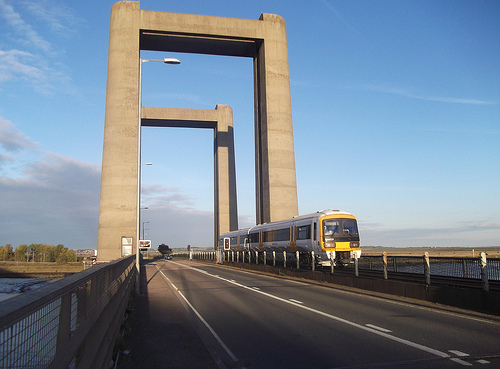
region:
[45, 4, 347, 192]
the arch is stone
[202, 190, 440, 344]
this is a train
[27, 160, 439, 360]
this is a bridge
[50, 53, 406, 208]
the sky is mostly clear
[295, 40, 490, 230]
the sky is light blue and white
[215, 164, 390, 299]
the train is yellow and white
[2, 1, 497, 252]
clouds in blue sky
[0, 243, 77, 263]
green trees on horizon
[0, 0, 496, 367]
top of paved bridge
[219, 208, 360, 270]
white and yellow commuter train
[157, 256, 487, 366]
white lines on paved road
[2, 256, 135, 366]
railing along side of bridge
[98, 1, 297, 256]
two cement structures on bridge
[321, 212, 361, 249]
windshield on front of train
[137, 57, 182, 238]
light on top of pole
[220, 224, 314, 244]
windows on side of train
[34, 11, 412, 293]
this is a highway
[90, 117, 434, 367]
this is a railroad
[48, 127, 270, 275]
this is a bridge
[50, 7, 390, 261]
the bridge has an arch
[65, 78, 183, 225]
the arch is stone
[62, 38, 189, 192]
the arch is gray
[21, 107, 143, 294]
the sky is cloudy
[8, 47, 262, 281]
the skys is light blue and clear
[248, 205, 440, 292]
the train is here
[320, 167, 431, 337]
the train is moving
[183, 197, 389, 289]
this is a train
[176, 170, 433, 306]
train on the tracks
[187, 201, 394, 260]
this is a passenger train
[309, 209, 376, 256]
yellow front of train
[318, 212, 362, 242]
front windows on train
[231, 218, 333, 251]
row of train windows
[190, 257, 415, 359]
white lines on road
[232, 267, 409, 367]
dashes lines on road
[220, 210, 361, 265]
train is yellow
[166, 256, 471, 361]
line is white and long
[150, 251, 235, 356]
line is white and long